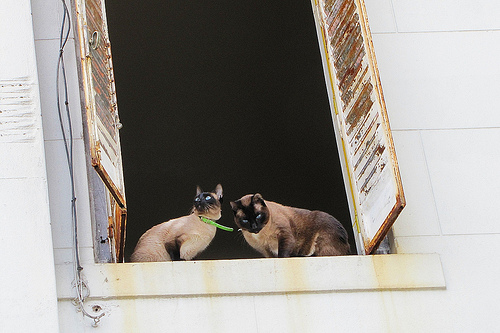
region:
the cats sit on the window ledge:
[130, 185, 360, 250]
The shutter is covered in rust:
[335, 16, 420, 246]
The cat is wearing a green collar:
[186, 207, 237, 238]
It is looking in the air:
[152, 166, 232, 226]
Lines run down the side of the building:
[56, 135, 104, 317]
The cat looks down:
[215, 157, 361, 266]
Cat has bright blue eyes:
[167, 173, 231, 230]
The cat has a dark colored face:
[229, 192, 280, 246]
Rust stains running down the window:
[360, 255, 405, 330]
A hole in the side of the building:
[84, 304, 104, 321]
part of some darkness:
[221, 112, 277, 156]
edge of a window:
[391, 160, 414, 228]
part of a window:
[350, 143, 419, 215]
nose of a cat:
[249, 216, 259, 230]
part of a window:
[348, 139, 379, 189]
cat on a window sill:
[221, 188, 358, 267]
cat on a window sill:
[123, 179, 233, 269]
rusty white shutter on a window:
[299, 0, 426, 260]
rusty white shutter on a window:
[57, 0, 139, 265]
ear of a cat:
[250, 190, 263, 203]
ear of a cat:
[225, 194, 240, 213]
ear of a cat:
[212, 178, 227, 201]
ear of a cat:
[192, 181, 204, 196]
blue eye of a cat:
[252, 211, 266, 222]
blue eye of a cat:
[202, 192, 217, 202]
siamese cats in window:
[146, 177, 345, 254]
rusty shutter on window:
[63, 0, 143, 229]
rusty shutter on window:
[311, 0, 408, 248]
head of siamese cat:
[192, 183, 228, 223]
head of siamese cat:
[229, 190, 273, 231]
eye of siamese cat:
[205, 195, 220, 205]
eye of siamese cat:
[191, 193, 200, 203]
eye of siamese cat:
[251, 208, 265, 223]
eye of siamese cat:
[238, 217, 253, 229]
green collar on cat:
[197, 215, 230, 232]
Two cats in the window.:
[121, 151, 351, 252]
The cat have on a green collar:
[171, 206, 226, 231]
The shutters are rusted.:
[78, 7, 145, 183]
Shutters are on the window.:
[63, 77, 413, 189]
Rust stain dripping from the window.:
[108, 270, 400, 321]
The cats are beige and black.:
[153, 199, 332, 252]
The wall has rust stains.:
[68, 253, 472, 330]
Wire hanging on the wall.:
[46, 1, 91, 228]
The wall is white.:
[406, 20, 483, 222]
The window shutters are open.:
[71, 12, 393, 197]